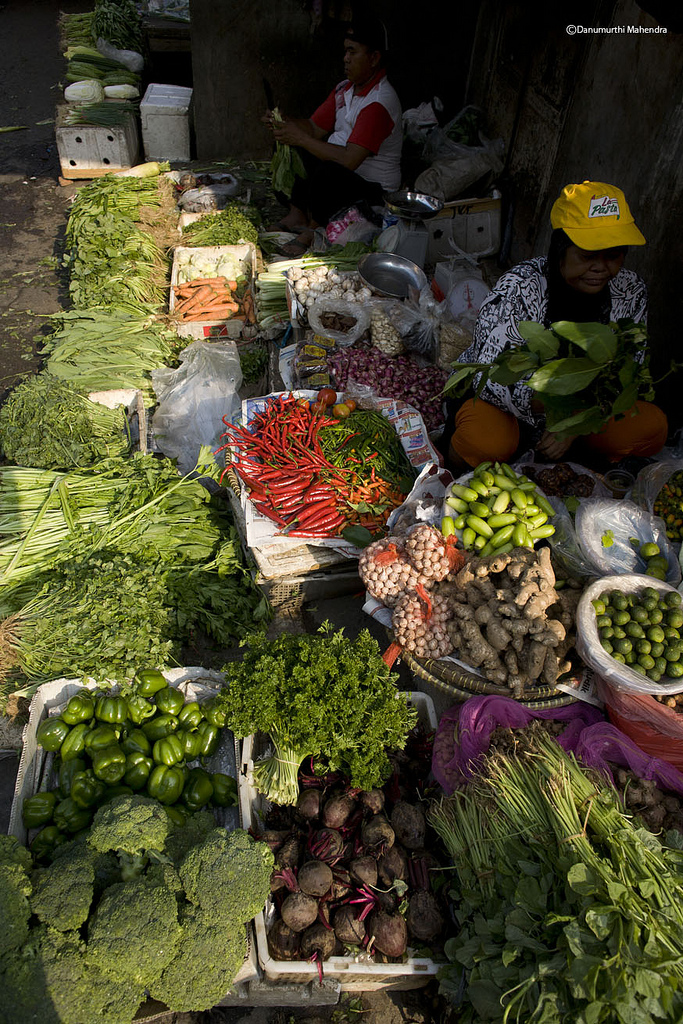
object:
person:
[442, 181, 668, 480]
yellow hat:
[550, 180, 647, 249]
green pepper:
[95, 693, 128, 725]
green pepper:
[59, 695, 95, 727]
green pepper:
[36, 718, 69, 751]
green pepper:
[92, 745, 127, 784]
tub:
[0, 666, 253, 1024]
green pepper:
[23, 791, 57, 827]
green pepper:
[148, 762, 186, 806]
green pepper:
[210, 774, 237, 810]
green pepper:
[182, 769, 214, 812]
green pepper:
[177, 703, 202, 733]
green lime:
[614, 608, 630, 625]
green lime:
[613, 638, 633, 655]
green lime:
[637, 652, 655, 669]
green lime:
[647, 622, 665, 642]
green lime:
[643, 595, 656, 611]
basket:
[589, 580, 683, 689]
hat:
[346, 0, 388, 49]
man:
[258, 2, 403, 259]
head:
[340, 0, 383, 87]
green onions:
[61, 99, 139, 126]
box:
[56, 96, 138, 179]